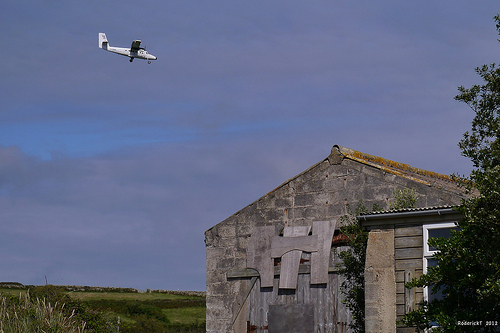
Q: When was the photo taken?
A: Daytime.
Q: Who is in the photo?
A: Nobody.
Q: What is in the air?
A: A plane.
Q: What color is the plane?
A: White.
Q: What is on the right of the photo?
A: A tree.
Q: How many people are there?
A: None.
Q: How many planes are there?
A: One.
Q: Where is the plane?
A: In the sky.